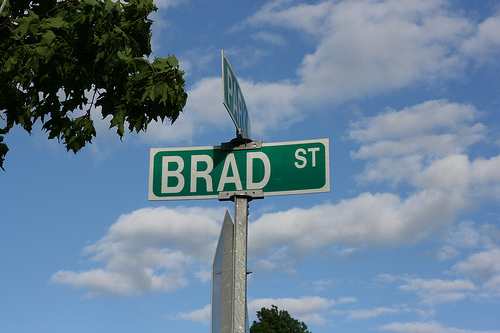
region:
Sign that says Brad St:
[143, 143, 327, 190]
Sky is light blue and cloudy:
[50, 162, 492, 317]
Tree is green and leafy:
[10, 8, 182, 138]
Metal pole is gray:
[229, 199, 249, 331]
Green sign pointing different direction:
[217, 62, 262, 136]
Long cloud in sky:
[293, 202, 443, 245]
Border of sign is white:
[262, 139, 333, 144]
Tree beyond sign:
[247, 300, 307, 330]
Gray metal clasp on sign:
[223, 135, 261, 151]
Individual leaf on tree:
[79, 115, 102, 137]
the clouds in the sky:
[325, 16, 495, 312]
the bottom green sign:
[146, 141, 327, 199]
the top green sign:
[217, 55, 268, 138]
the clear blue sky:
[14, 173, 90, 231]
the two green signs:
[140, 49, 337, 204]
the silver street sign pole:
[211, 192, 254, 329]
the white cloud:
[325, 25, 386, 83]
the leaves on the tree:
[2, 2, 182, 155]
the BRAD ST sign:
[150, 143, 325, 196]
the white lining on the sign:
[145, 136, 342, 202]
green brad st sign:
[154, 137, 330, 202]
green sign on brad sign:
[223, 67, 258, 138]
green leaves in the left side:
[4, 1, 181, 156]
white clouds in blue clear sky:
[88, 0, 493, 302]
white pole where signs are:
[229, 199, 245, 331]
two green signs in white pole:
[156, 63, 331, 195]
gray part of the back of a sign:
[210, 209, 237, 331]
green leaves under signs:
[248, 305, 304, 331]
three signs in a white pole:
[147, 51, 327, 325]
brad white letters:
[158, 147, 270, 193]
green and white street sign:
[143, 146, 352, 207]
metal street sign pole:
[217, 197, 275, 332]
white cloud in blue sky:
[347, 99, 487, 255]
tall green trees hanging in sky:
[0, 26, 197, 177]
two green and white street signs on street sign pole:
[141, 50, 332, 225]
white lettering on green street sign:
[157, 150, 182, 196]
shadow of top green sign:
[209, 129, 248, 169]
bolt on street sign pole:
[240, 261, 256, 281]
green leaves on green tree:
[68, 108, 106, 163]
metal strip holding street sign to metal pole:
[212, 186, 271, 205]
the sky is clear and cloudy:
[330, 73, 475, 213]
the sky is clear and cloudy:
[238, 33, 415, 324]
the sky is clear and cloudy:
[308, 133, 488, 331]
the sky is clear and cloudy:
[246, 86, 491, 178]